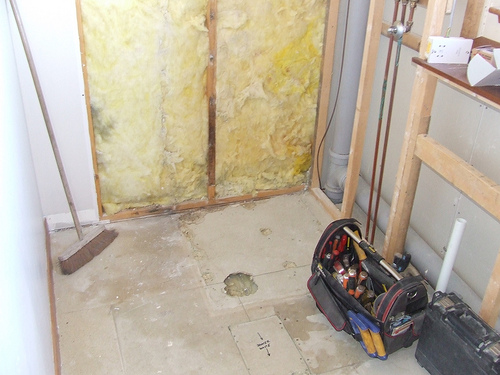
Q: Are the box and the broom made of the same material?
A: No, the box is made of plastic and the broom is made of wood.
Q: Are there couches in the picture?
A: No, there are no couches.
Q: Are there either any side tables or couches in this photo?
A: No, there are no couches or side tables.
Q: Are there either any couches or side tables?
A: No, there are no couches or side tables.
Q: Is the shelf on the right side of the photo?
A: Yes, the shelf is on the right of the image.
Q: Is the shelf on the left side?
A: No, the shelf is on the right of the image.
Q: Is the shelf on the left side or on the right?
A: The shelf is on the right of the image.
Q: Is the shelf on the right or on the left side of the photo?
A: The shelf is on the right of the image.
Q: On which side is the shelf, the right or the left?
A: The shelf is on the right of the image.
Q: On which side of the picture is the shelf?
A: The shelf is on the right of the image.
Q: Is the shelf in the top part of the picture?
A: Yes, the shelf is in the top of the image.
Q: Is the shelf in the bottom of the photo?
A: No, the shelf is in the top of the image.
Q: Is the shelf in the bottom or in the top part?
A: The shelf is in the top of the image.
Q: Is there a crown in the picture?
A: No, there are no crowns.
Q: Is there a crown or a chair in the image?
A: No, there are no crowns or chairs.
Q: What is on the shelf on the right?
A: The outlet is on the shelf.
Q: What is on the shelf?
A: The outlet is on the shelf.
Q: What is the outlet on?
A: The outlet is on the shelf.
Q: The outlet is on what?
A: The outlet is on the shelf.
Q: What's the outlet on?
A: The outlet is on the shelf.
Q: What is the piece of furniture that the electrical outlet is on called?
A: The piece of furniture is a shelf.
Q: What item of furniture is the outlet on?
A: The electrical outlet is on the shelf.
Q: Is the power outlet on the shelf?
A: Yes, the power outlet is on the shelf.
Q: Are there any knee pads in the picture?
A: No, there are no knee pads.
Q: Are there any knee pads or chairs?
A: No, there are no knee pads or chairs.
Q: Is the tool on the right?
A: Yes, the tool is on the right of the image.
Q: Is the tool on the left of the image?
A: No, the tool is on the right of the image.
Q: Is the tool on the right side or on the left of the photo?
A: The tool is on the right of the image.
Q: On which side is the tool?
A: The tool is on the right of the image.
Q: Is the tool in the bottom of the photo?
A: Yes, the tool is in the bottom of the image.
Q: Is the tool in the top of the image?
A: No, the tool is in the bottom of the image.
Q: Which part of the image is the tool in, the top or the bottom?
A: The tool is in the bottom of the image.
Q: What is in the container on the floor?
A: The tool is in the box.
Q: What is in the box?
A: The tool is in the box.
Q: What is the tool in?
A: The tool is in the box.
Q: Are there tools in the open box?
A: Yes, there is a tool in the box.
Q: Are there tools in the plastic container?
A: Yes, there is a tool in the box.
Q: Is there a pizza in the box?
A: No, there is a tool in the box.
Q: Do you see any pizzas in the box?
A: No, there is a tool in the box.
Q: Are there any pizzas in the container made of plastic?
A: No, there is a tool in the box.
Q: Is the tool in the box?
A: Yes, the tool is in the box.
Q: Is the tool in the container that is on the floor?
A: Yes, the tool is in the box.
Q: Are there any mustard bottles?
A: No, there are no mustard bottles.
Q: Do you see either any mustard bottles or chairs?
A: No, there are no mustard bottles or chairs.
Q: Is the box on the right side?
A: Yes, the box is on the right of the image.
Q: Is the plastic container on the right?
A: Yes, the box is on the right of the image.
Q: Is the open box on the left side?
A: No, the box is on the right of the image.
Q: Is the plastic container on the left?
A: No, the box is on the right of the image.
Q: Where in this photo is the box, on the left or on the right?
A: The box is on the right of the image.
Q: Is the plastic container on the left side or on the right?
A: The box is on the right of the image.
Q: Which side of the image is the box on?
A: The box is on the right of the image.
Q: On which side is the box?
A: The box is on the right of the image.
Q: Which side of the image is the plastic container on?
A: The box is on the right of the image.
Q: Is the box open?
A: Yes, the box is open.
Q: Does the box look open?
A: Yes, the box is open.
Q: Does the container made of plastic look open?
A: Yes, the box is open.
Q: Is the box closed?
A: No, the box is open.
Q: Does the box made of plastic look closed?
A: No, the box is open.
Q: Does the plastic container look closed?
A: No, the box is open.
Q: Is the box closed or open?
A: The box is open.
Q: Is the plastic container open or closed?
A: The box is open.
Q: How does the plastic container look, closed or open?
A: The box is open.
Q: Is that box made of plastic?
A: Yes, the box is made of plastic.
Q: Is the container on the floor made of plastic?
A: Yes, the box is made of plastic.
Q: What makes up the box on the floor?
A: The box is made of plastic.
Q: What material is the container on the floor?
A: The box is made of plastic.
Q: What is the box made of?
A: The box is made of plastic.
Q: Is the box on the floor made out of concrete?
A: No, the box is made of plastic.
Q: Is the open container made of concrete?
A: No, the box is made of plastic.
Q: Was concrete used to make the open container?
A: No, the box is made of plastic.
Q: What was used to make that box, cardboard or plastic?
A: The box is made of plastic.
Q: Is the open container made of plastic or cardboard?
A: The box is made of plastic.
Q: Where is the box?
A: The box is on the floor.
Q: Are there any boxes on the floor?
A: Yes, there is a box on the floor.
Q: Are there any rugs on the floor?
A: No, there is a box on the floor.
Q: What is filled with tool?
A: The box is filled with tool.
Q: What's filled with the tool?
A: The box is filled with tool.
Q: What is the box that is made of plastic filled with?
A: The box is filled with tool.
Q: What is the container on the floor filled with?
A: The box is filled with tool.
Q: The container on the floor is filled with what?
A: The box is filled with tool.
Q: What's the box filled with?
A: The box is filled with tool.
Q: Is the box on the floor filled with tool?
A: Yes, the box is filled with tool.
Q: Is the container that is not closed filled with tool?
A: Yes, the box is filled with tool.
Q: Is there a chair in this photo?
A: No, there are no chairs.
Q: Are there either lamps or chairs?
A: No, there are no chairs or lamps.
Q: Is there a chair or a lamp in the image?
A: No, there are no chairs or lamps.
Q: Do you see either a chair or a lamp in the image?
A: No, there are no chairs or lamps.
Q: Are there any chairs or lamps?
A: No, there are no chairs or lamps.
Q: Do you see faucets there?
A: No, there are no faucets.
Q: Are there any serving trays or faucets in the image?
A: No, there are no faucets or serving trays.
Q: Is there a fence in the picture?
A: No, there are no fences.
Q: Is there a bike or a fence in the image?
A: No, there are no fences or bikes.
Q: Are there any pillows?
A: No, there are no pillows.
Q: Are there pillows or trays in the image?
A: No, there are no pillows or trays.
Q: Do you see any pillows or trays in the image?
A: No, there are no pillows or trays.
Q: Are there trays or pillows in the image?
A: No, there are no pillows or trays.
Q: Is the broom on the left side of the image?
A: Yes, the broom is on the left of the image.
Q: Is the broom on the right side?
A: No, the broom is on the left of the image.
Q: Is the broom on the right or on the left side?
A: The broom is on the left of the image.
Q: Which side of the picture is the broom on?
A: The broom is on the left of the image.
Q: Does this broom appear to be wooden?
A: Yes, the broom is wooden.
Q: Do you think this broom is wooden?
A: Yes, the broom is wooden.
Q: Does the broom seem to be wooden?
A: Yes, the broom is wooden.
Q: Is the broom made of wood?
A: Yes, the broom is made of wood.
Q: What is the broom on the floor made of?
A: The broom is made of wood.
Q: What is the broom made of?
A: The broom is made of wood.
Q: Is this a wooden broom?
A: Yes, this is a wooden broom.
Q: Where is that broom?
A: The broom is on the floor.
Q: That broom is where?
A: The broom is on the floor.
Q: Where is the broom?
A: The broom is on the floor.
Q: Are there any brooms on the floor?
A: Yes, there is a broom on the floor.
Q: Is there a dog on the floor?
A: No, there is a broom on the floor.